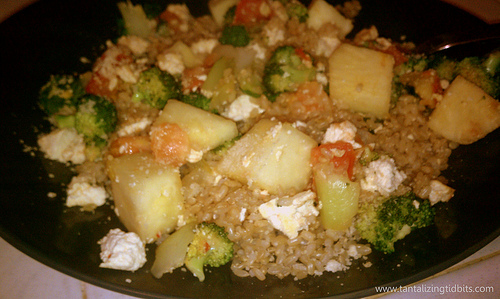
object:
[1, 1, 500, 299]
plate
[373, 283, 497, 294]
logo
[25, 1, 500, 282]
food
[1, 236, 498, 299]
cloth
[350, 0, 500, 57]
spoon